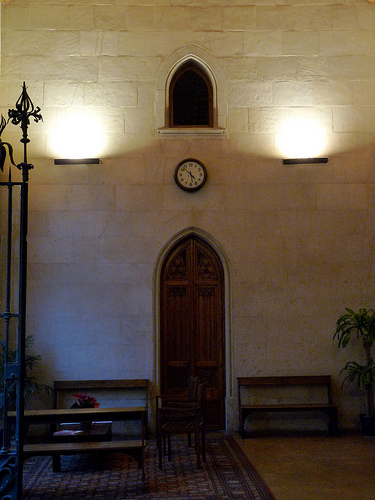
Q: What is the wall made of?
A: White stone.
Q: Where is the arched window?
A: Above the door.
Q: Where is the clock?
A: Above the door.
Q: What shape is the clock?
A: Round.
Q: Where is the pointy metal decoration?
A: On the left.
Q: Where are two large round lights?
A: On the wall.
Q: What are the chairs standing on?
A: Carpet.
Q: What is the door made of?
A: Wood.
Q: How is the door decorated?
A: Carved.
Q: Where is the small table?
A: Between two benches on the left.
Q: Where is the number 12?
A: On the clock.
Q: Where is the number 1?
A: On the clock.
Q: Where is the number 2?
A: On the clock.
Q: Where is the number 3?
A: On the clock.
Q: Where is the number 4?
A: On the clock.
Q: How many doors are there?
A: One.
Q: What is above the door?
A: A clock.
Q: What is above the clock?
A: A window.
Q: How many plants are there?
A: Two.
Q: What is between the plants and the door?
A: Benches.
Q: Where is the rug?
A: On the floor.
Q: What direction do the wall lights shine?
A: Up.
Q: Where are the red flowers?
A: On the table.